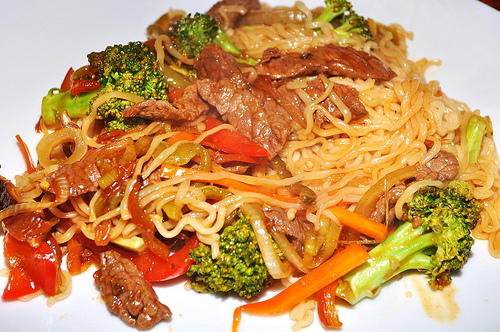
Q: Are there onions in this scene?
A: Yes, there is an onion.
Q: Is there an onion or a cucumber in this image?
A: Yes, there is an onion.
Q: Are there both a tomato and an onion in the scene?
A: No, there is an onion but no tomatoes.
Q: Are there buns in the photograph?
A: No, there are no buns.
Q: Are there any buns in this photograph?
A: No, there are no buns.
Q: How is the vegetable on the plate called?
A: The vegetable is an onion.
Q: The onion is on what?
A: The onion is on the plate.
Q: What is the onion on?
A: The onion is on the plate.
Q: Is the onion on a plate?
A: Yes, the onion is on a plate.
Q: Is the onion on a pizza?
A: No, the onion is on a plate.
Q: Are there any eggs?
A: No, there are no eggs.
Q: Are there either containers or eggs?
A: No, there are no eggs or containers.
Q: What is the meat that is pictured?
A: The meat is beef.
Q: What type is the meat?
A: The meat is beef.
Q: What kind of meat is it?
A: The meat is beef.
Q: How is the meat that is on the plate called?
A: The meat is beef.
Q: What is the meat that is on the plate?
A: The meat is beef.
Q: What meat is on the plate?
A: The meat is beef.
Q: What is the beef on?
A: The beef is on the plate.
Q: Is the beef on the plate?
A: Yes, the beef is on the plate.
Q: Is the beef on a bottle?
A: No, the beef is on the plate.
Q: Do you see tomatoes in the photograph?
A: No, there are no tomatoes.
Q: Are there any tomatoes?
A: No, there are no tomatoes.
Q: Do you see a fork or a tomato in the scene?
A: No, there are no tomatoes or forks.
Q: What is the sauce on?
A: The sauce is on the plate.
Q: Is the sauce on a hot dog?
A: No, the sauce is on the plate.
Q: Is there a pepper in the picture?
A: Yes, there is a pepper.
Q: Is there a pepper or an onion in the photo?
A: Yes, there is a pepper.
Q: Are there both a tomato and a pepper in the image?
A: No, there is a pepper but no tomatoes.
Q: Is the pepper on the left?
A: Yes, the pepper is on the left of the image.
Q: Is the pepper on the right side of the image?
A: No, the pepper is on the left of the image.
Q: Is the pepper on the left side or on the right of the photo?
A: The pepper is on the left of the image.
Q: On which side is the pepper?
A: The pepper is on the left of the image.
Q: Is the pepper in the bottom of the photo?
A: Yes, the pepper is in the bottom of the image.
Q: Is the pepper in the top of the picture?
A: No, the pepper is in the bottom of the image.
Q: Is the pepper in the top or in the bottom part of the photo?
A: The pepper is in the bottom of the image.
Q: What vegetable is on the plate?
A: The vegetable is a pepper.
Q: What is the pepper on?
A: The pepper is on the plate.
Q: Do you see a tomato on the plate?
A: No, there is a pepper on the plate.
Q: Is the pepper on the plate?
A: Yes, the pepper is on the plate.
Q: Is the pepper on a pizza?
A: No, the pepper is on the plate.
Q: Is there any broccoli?
A: Yes, there is broccoli.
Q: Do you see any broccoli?
A: Yes, there is broccoli.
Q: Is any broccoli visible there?
A: Yes, there is broccoli.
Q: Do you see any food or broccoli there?
A: Yes, there is broccoli.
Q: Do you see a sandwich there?
A: No, there are no sandwiches.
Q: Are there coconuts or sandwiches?
A: No, there are no sandwiches or coconuts.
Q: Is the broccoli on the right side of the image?
A: Yes, the broccoli is on the right of the image.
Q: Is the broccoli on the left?
A: No, the broccoli is on the right of the image.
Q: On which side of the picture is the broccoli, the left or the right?
A: The broccoli is on the right of the image.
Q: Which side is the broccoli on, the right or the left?
A: The broccoli is on the right of the image.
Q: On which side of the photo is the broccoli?
A: The broccoli is on the right of the image.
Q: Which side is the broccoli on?
A: The broccoli is on the right of the image.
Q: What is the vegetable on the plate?
A: The vegetable is broccoli.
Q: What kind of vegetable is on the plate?
A: The vegetable is broccoli.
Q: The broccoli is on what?
A: The broccoli is on the plate.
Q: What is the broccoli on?
A: The broccoli is on the plate.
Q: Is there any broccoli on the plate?
A: Yes, there is broccoli on the plate.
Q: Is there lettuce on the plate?
A: No, there is broccoli on the plate.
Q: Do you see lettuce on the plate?
A: No, there is broccoli on the plate.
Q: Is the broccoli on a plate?
A: Yes, the broccoli is on a plate.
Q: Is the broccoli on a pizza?
A: No, the broccoli is on a plate.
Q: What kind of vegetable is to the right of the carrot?
A: The vegetable is broccoli.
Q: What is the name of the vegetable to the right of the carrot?
A: The vegetable is broccoli.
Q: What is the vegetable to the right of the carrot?
A: The vegetable is broccoli.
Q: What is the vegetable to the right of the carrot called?
A: The vegetable is broccoli.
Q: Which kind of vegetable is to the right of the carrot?
A: The vegetable is broccoli.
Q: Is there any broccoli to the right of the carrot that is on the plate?
A: Yes, there is broccoli to the right of the carrot.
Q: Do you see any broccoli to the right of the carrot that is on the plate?
A: Yes, there is broccoli to the right of the carrot.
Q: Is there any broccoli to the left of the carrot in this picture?
A: No, the broccoli is to the right of the carrot.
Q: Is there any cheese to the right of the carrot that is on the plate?
A: No, there is broccoli to the right of the carrot.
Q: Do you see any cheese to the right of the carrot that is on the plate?
A: No, there is broccoli to the right of the carrot.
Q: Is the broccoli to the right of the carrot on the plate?
A: Yes, the broccoli is to the right of the carrot.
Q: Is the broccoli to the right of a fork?
A: No, the broccoli is to the right of the carrot.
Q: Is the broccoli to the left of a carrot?
A: No, the broccoli is to the right of a carrot.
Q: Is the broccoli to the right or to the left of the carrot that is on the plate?
A: The broccoli is to the right of the carrot.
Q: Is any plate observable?
A: Yes, there is a plate.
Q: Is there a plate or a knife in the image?
A: Yes, there is a plate.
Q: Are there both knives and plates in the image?
A: No, there is a plate but no knives.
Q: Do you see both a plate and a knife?
A: No, there is a plate but no knives.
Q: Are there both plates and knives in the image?
A: No, there is a plate but no knives.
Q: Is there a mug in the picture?
A: No, there are no mugs.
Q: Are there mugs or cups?
A: No, there are no mugs or cups.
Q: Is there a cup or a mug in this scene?
A: No, there are no mugs or cups.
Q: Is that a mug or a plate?
A: That is a plate.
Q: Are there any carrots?
A: Yes, there is a carrot.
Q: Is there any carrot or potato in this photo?
A: Yes, there is a carrot.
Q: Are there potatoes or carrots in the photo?
A: Yes, there is a carrot.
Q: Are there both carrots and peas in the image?
A: No, there is a carrot but no peas.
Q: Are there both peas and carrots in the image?
A: No, there is a carrot but no peas.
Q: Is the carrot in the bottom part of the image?
A: Yes, the carrot is in the bottom of the image.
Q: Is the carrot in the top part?
A: No, the carrot is in the bottom of the image.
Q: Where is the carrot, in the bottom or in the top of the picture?
A: The carrot is in the bottom of the image.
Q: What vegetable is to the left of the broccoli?
A: The vegetable is a carrot.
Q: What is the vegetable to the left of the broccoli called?
A: The vegetable is a carrot.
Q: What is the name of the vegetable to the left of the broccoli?
A: The vegetable is a carrot.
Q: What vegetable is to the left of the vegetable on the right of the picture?
A: The vegetable is a carrot.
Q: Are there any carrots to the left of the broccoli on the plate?
A: Yes, there is a carrot to the left of the broccoli.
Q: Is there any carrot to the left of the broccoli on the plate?
A: Yes, there is a carrot to the left of the broccoli.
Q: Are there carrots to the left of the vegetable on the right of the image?
A: Yes, there is a carrot to the left of the broccoli.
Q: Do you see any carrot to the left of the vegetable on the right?
A: Yes, there is a carrot to the left of the broccoli.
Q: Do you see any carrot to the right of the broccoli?
A: No, the carrot is to the left of the broccoli.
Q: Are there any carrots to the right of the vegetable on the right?
A: No, the carrot is to the left of the broccoli.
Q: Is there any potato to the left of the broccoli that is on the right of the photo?
A: No, there is a carrot to the left of the broccoli.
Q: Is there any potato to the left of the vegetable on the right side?
A: No, there is a carrot to the left of the broccoli.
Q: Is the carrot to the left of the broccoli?
A: Yes, the carrot is to the left of the broccoli.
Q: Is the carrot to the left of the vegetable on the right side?
A: Yes, the carrot is to the left of the broccoli.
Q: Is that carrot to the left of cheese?
A: No, the carrot is to the left of the broccoli.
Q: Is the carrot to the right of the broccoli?
A: No, the carrot is to the left of the broccoli.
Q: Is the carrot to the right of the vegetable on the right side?
A: No, the carrot is to the left of the broccoli.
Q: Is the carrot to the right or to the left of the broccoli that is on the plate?
A: The carrot is to the left of the broccoli.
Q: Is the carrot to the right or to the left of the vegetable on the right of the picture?
A: The carrot is to the left of the broccoli.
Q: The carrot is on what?
A: The carrot is on the plate.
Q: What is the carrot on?
A: The carrot is on the plate.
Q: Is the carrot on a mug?
A: No, the carrot is on the plate.